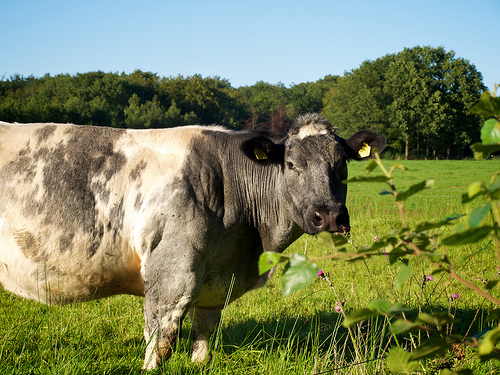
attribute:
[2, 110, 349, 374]
cow — large, huge, looking, old, white, black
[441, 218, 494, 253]
leaf — green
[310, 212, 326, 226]
nostril — large, round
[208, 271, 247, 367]
grass leaf — tall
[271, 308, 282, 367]
grass leaf — tall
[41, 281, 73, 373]
grass leaf — tall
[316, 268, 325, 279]
flower — small, purple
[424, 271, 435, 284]
flower — pink, small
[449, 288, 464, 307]
flower — pink, purple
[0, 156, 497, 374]
meadow — bright green, open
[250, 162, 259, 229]
wrinkle — vertical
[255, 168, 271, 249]
wrinkle — vertical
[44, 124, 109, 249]
marking — gray, large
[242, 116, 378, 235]
head — turned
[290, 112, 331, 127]
hair — fuzzy, gray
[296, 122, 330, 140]
crown — white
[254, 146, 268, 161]
tag — yellow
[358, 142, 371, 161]
tag — yellow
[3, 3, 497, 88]
sky — cloudless, light blue, blue